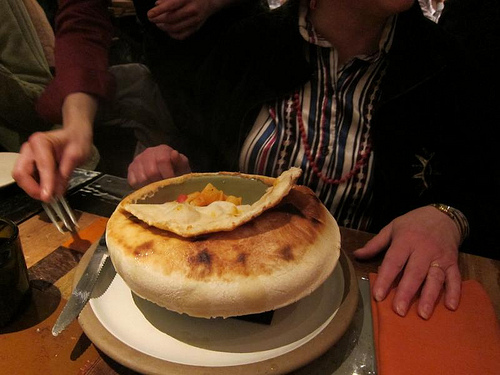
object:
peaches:
[223, 193, 244, 208]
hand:
[124, 142, 191, 191]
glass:
[0, 215, 34, 331]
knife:
[50, 229, 111, 338]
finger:
[443, 263, 461, 313]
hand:
[352, 204, 462, 321]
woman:
[126, 0, 500, 323]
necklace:
[293, 89, 381, 187]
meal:
[105, 169, 345, 321]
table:
[0, 171, 499, 375]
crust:
[101, 164, 343, 320]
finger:
[351, 220, 392, 261]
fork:
[41, 189, 81, 236]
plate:
[87, 257, 349, 370]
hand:
[10, 126, 93, 205]